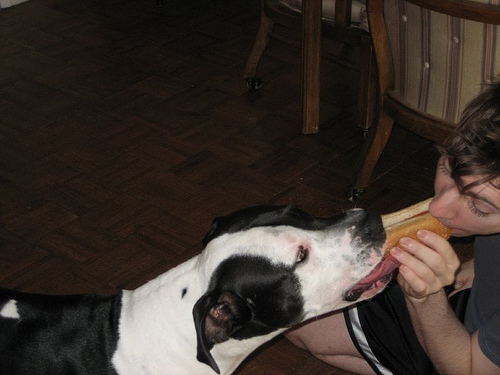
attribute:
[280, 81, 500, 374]
man — sharing, holding, biting, eating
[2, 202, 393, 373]
dog — biting, sharing, eating, inside, black colro, black, white colo, white, black colo, white color, black color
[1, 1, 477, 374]
floor — part, wooden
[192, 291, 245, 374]
ear — black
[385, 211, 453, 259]
hotdog — part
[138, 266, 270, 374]
neck — white